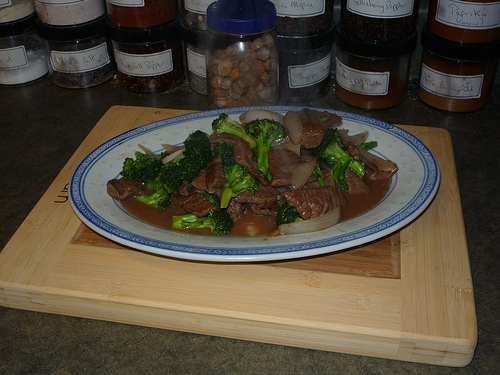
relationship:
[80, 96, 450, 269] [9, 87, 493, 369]
plate on board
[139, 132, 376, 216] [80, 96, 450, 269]
food on plate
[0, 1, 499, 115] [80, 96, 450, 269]
jars near plate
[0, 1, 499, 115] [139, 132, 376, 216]
jars near food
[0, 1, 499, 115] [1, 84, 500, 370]
jars on counter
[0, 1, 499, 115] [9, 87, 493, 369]
jars near board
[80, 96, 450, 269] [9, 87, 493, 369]
plate on top of board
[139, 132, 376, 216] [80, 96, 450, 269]
food on top of plate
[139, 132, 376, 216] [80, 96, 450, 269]
food over plate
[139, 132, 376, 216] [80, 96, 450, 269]
food in plate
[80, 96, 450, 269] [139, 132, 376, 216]
plate under food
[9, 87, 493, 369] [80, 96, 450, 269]
board under plate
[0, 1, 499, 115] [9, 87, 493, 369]
jars by board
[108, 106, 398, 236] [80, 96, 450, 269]
beef on plate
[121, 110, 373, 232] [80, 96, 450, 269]
broccoli on plate